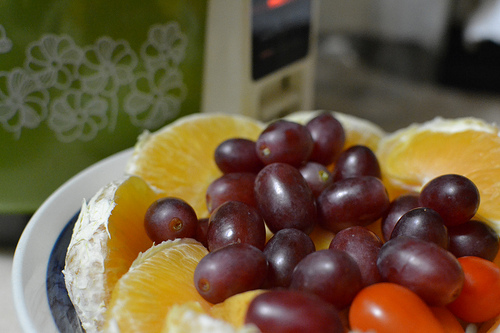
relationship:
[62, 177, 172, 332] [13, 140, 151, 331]
orange slice on plate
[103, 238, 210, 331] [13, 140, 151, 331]
orange slice on plate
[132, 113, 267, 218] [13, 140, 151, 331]
orange slice on plate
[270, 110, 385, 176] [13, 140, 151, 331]
orange slice on plate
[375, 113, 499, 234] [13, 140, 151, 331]
orange slice on plate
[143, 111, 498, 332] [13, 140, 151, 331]
grapes on plate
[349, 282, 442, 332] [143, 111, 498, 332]
tomato beside grapes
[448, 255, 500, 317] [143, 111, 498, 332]
tomato beside grapes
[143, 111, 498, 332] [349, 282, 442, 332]
grapes near tomato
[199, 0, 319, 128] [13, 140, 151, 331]
appliance near plate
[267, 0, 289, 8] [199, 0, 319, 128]
light on appliance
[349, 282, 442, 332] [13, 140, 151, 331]
tomato on plate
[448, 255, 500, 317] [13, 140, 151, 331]
tomato on plate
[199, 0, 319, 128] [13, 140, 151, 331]
appliance behind plate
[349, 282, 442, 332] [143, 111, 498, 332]
tomato next to grapes